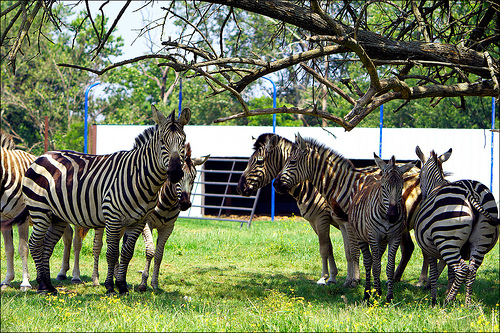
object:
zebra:
[20, 105, 194, 296]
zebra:
[411, 146, 498, 303]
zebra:
[347, 153, 419, 306]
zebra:
[272, 132, 451, 289]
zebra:
[235, 132, 418, 286]